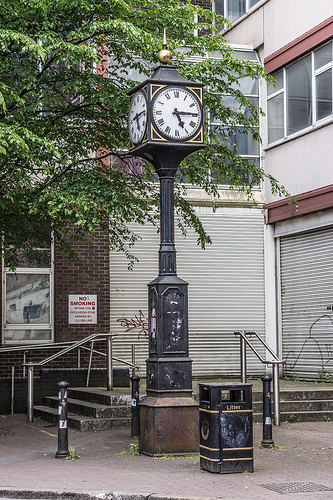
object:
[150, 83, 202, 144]
clock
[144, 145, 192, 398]
post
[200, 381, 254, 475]
trash can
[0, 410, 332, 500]
ground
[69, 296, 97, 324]
sign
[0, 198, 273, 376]
wall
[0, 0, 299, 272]
tree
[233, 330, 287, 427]
railing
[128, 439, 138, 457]
weed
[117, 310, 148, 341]
graffiti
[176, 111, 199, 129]
hands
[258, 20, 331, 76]
frame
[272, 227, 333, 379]
door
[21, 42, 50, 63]
leaves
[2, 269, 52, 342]
window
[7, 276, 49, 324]
refelection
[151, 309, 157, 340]
stickers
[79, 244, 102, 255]
bricks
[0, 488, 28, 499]
edge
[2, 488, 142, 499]
curb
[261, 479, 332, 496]
grate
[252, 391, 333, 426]
steps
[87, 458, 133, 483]
bricks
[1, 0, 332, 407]
building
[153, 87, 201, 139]
clock face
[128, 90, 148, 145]
clock